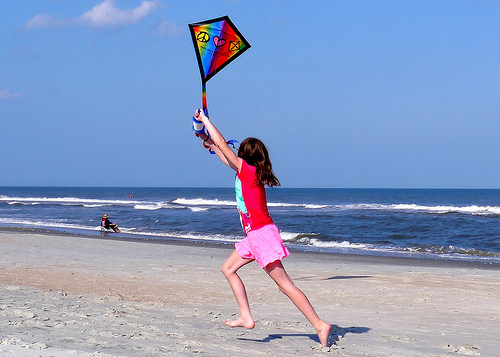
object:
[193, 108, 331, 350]
girl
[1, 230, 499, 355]
beach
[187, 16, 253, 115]
kite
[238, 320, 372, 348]
shadow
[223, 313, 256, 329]
foot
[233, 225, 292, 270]
shorts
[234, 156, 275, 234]
shirt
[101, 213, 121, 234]
person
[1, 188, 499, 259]
water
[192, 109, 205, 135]
handle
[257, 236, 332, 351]
legs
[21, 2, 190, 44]
clouds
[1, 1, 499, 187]
sky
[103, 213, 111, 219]
hat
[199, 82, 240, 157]
tail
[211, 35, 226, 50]
heart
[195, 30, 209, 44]
peace sign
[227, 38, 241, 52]
kite design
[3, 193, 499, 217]
wave